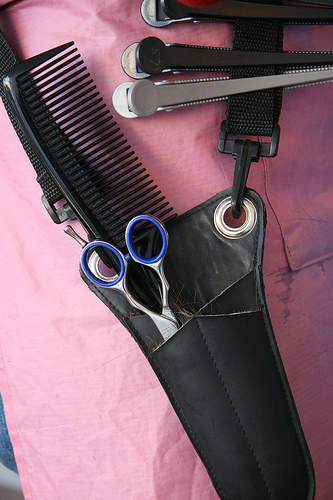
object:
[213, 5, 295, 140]
strap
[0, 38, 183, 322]
comb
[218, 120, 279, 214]
clip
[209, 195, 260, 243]
ring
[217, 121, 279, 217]
plastic clip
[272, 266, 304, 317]
stain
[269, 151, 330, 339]
cloth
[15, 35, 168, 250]
tooth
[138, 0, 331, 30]
hair clip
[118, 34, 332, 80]
hair clip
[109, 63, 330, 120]
hair clip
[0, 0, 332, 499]
apron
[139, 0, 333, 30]
tools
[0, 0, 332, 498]
pouch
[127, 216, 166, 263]
ring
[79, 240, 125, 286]
ring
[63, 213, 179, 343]
scissor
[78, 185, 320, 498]
case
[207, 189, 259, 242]
hole